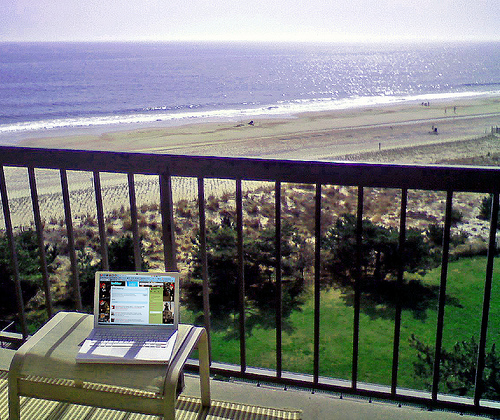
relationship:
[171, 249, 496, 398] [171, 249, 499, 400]
lawn has lawn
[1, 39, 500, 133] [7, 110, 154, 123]
ocean has wave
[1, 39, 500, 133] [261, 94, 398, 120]
ocean has wave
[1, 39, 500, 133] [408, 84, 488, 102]
ocean has wave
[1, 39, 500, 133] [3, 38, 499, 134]
ocean has water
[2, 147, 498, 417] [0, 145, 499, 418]
balcony has balcony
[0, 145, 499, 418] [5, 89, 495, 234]
balcony in front of beach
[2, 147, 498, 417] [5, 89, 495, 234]
balcony overlooking beach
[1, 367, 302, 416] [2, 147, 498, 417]
carpet on balcony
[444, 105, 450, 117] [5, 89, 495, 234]
person on beach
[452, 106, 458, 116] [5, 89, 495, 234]
person on beach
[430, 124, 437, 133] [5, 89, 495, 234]
person on beach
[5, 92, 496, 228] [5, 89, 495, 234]
sand on beach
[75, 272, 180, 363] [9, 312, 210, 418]
laptop on table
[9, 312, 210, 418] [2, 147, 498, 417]
table on balcony